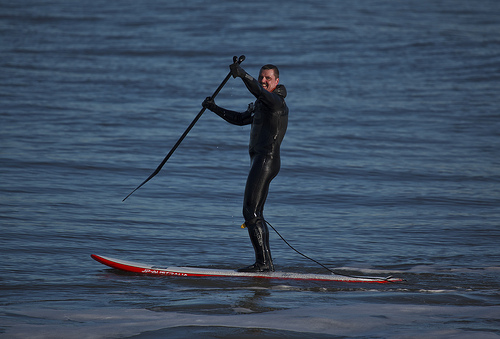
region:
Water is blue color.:
[332, 69, 452, 208]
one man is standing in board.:
[193, 55, 300, 270]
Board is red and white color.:
[85, 243, 398, 285]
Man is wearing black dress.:
[205, 61, 290, 271]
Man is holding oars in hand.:
[125, 38, 250, 194]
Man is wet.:
[180, 55, 306, 260]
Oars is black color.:
[125, 45, 240, 201]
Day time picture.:
[15, 15, 467, 315]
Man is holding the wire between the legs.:
[240, 205, 401, 275]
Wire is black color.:
[273, 225, 343, 280]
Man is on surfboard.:
[83, 30, 418, 304]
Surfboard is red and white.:
[81, 241, 406, 303]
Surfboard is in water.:
[78, 230, 412, 314]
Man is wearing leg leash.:
[98, 37, 439, 307]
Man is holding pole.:
[66, 40, 443, 308]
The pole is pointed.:
[61, 32, 443, 312]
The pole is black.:
[79, 29, 429, 301]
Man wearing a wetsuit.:
[114, 24, 311, 295]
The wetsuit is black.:
[84, 18, 306, 285]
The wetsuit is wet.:
[95, 36, 316, 306]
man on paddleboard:
[114, 46, 361, 283]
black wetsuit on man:
[228, 90, 293, 270]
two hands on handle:
[182, 54, 244, 137]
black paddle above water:
[105, 111, 208, 223]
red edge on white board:
[97, 249, 207, 286]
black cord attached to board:
[274, 222, 356, 281]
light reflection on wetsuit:
[258, 149, 275, 182]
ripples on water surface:
[94, 18, 170, 68]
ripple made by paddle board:
[389, 278, 465, 299]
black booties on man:
[233, 251, 274, 278]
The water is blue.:
[330, 62, 472, 228]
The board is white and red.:
[84, 226, 275, 337]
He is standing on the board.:
[97, 49, 366, 300]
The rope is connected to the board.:
[242, 193, 359, 315]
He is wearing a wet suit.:
[129, 63, 402, 303]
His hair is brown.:
[227, 51, 319, 109]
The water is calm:
[57, 36, 149, 131]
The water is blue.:
[34, 56, 111, 124]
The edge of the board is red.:
[64, 233, 437, 315]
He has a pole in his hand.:
[104, 51, 296, 209]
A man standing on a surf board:
[81, 10, 317, 303]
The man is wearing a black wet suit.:
[238, 100, 277, 210]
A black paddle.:
[109, 151, 187, 195]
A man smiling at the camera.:
[257, 64, 287, 104]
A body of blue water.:
[60, 58, 196, 232]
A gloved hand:
[232, 64, 252, 84]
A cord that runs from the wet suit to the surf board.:
[272, 228, 293, 252]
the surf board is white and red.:
[101, 237, 352, 289]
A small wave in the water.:
[10, 128, 399, 184]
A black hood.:
[278, 85, 290, 98]